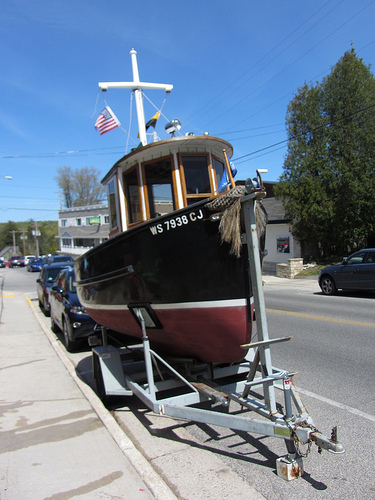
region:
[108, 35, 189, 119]
cross on a ship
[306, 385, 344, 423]
white line on street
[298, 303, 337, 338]
yellow line on the ground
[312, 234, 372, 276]
car parked on the street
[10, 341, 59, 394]
sidewalk next to the street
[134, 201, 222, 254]
white letters on the boat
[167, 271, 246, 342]
red, white and black boat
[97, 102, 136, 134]
American flag on boat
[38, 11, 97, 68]
blue sky above the land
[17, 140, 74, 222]
wires above the land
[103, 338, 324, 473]
Grey metal trailer under boat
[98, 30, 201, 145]
White cross as mast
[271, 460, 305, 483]
Cement block under trailer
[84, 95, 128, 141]
American flag above boat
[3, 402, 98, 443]
Water marks on sidewalk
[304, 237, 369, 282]
Blue car across the street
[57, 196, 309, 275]
White buildings in background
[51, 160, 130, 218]
Tall brown trees behind building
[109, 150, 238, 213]
Wooden boat cabin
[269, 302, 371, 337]
Yellow line dividing lanes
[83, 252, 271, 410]
a boat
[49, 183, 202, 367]
a boat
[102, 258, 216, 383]
a boat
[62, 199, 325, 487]
a boat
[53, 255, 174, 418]
a boat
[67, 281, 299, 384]
Red on a boat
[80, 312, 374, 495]
Trailer under a boat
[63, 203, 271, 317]
Black on a boat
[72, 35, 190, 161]
Mast on a boat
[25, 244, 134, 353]
Two cars parked behind a boat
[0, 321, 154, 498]
Gray sidewalk by a boat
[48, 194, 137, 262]
Building by a road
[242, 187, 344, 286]
White building by a road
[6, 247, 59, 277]
Cars driving on a road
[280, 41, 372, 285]
Green tree by a road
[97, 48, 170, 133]
White cross as mast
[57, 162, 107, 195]
Brown trees behind building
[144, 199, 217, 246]
Identification of boat on side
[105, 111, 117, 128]
American flag above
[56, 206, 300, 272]
Building in background behind boat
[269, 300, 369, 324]
Yellow lane dividing lanes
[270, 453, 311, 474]
Cement block under trailer